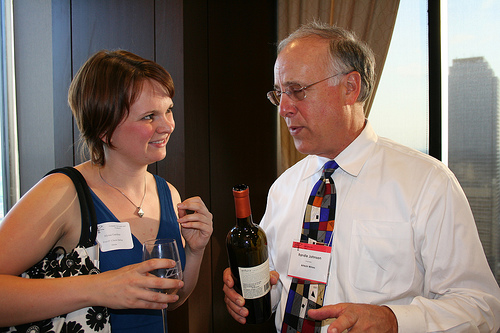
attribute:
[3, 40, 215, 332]
woman — talking, smiling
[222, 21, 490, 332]
man — closing eyes, talking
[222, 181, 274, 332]
bottle — wine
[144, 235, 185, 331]
glass — wine glass, empty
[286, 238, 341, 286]
nametag — white, orange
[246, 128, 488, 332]
shirt — long sleeved, white, button down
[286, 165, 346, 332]
tie — multi-colored, colorful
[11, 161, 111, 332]
purse — white, black, flowered, brown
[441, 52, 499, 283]
building — skyscraper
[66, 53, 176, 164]
hair — brown, short, red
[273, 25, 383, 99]
hair — gray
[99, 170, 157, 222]
necklace — silver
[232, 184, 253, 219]
neck — red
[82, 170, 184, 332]
dress — blue